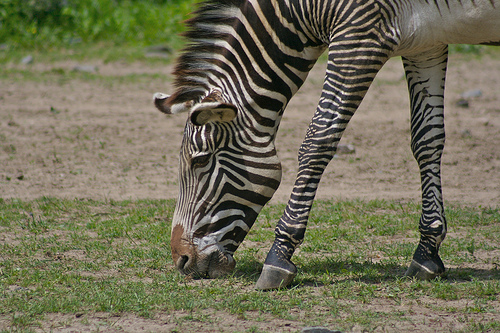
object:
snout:
[168, 222, 239, 279]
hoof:
[254, 256, 299, 291]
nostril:
[177, 253, 191, 271]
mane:
[163, 0, 248, 107]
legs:
[268, 38, 394, 251]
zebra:
[151, 0, 500, 292]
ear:
[189, 101, 241, 128]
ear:
[149, 91, 192, 117]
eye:
[188, 150, 217, 173]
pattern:
[217, 152, 282, 171]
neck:
[192, 0, 328, 141]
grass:
[1, 1, 484, 83]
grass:
[0, 197, 500, 332]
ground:
[0, 40, 500, 332]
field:
[0, 47, 500, 332]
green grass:
[0, 193, 500, 332]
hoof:
[403, 256, 446, 282]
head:
[152, 86, 285, 279]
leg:
[400, 44, 455, 258]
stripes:
[289, 192, 318, 204]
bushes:
[2, 1, 188, 51]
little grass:
[248, 324, 259, 332]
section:
[0, 196, 500, 333]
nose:
[169, 233, 196, 276]